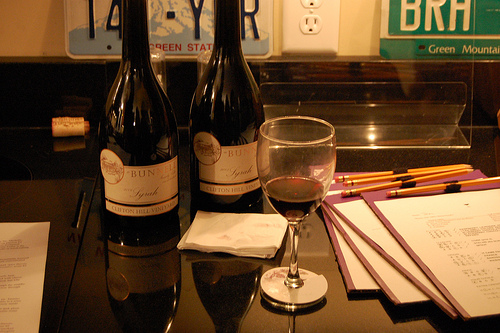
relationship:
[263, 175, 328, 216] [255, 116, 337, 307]
wine in glass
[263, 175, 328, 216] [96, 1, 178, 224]
wine in bottle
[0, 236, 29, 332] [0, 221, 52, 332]
black print paper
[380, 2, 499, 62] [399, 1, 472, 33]
license plate white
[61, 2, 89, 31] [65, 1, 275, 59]
white on blue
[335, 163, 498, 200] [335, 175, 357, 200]
pencils have erasers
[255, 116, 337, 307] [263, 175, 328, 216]
glass of wine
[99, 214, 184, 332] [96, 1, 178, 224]
reflection of bottle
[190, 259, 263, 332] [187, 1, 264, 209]
reflection of bottle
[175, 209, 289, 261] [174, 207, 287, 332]
napkin on table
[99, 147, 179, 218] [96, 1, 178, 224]
lable on bottle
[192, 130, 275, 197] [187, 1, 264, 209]
lable on bottle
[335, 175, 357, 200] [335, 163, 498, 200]
erasers on pencils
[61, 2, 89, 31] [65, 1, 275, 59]
white license blue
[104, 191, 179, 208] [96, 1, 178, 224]
line on bottle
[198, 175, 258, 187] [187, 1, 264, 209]
line on bottle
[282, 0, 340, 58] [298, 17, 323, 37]
electrical wall plug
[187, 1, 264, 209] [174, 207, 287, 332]
bottle on table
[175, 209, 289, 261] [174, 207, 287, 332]
napkins on table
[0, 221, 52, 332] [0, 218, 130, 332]
paper on table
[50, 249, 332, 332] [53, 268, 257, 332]
black shiny table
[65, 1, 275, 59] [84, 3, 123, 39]
license with numbers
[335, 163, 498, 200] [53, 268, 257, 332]
pencils on table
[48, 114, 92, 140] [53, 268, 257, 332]
cork on table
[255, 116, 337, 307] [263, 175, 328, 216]
glass with wine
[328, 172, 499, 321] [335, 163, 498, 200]
clipboards with pencils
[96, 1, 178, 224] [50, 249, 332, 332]
bottle on tables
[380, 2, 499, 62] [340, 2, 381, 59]
plate against wall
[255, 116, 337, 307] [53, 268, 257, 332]
glass on table